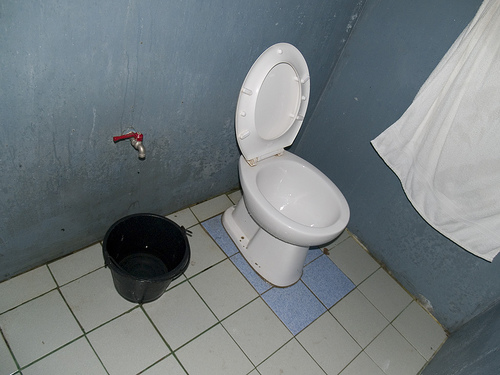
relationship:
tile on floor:
[0, 264, 57, 312] [4, 190, 444, 370]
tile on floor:
[3, 285, 93, 368] [4, 190, 444, 370]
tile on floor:
[18, 332, 108, 371] [4, 190, 444, 370]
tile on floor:
[81, 301, 171, 371] [4, 190, 444, 370]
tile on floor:
[57, 264, 139, 333] [4, 190, 444, 370]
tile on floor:
[140, 277, 216, 353] [4, 190, 444, 370]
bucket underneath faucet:
[95, 207, 198, 311] [114, 123, 151, 163]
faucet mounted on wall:
[111, 125, 151, 166] [2, 0, 363, 286]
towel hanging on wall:
[365, 0, 498, 269] [285, 3, 495, 337]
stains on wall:
[24, 107, 116, 198] [2, 0, 363, 286]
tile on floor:
[5, 177, 452, 371] [5, 178, 456, 374]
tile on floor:
[184, 254, 263, 324] [5, 178, 456, 374]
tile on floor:
[216, 292, 297, 367] [5, 178, 456, 374]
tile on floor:
[296, 314, 363, 374] [5, 178, 456, 374]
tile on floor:
[395, 294, 456, 368] [4, 190, 444, 370]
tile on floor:
[295, 306, 364, 371] [5, 178, 456, 374]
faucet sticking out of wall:
[111, 125, 151, 166] [2, 0, 363, 286]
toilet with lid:
[215, 36, 353, 291] [228, 40, 314, 169]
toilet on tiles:
[215, 36, 353, 291] [198, 194, 375, 335]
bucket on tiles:
[95, 207, 198, 311] [6, 171, 450, 373]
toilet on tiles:
[220, 41, 359, 293] [201, 199, 366, 339]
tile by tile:
[5, 177, 452, 371] [192, 186, 369, 344]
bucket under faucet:
[95, 207, 198, 311] [111, 125, 151, 166]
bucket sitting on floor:
[95, 207, 198, 311] [4, 190, 444, 370]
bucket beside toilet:
[95, 207, 198, 311] [228, 36, 358, 288]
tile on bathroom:
[263, 274, 330, 335] [5, 1, 494, 373]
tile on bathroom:
[225, 285, 295, 374] [5, 1, 494, 373]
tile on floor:
[225, 285, 295, 374] [4, 190, 444, 370]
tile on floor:
[141, 281, 225, 345] [5, 178, 456, 374]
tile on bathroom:
[141, 281, 225, 345] [5, 1, 494, 373]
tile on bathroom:
[170, 327, 260, 373] [5, 1, 494, 373]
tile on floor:
[170, 327, 260, 373] [4, 190, 444, 370]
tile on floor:
[80, 297, 176, 371] [5, 178, 456, 374]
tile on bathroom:
[80, 297, 176, 371] [5, 1, 494, 373]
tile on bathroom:
[0, 290, 90, 370] [5, 1, 494, 373]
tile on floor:
[0, 290, 90, 370] [4, 190, 444, 370]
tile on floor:
[199, 206, 241, 253] [4, 190, 444, 370]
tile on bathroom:
[199, 206, 241, 253] [5, 1, 494, 373]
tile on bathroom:
[389, 295, 457, 360] [5, 1, 494, 373]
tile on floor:
[389, 295, 457, 360] [5, 178, 456, 374]